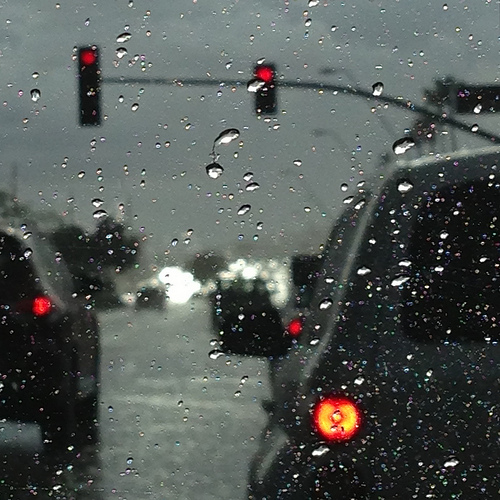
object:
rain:
[180, 117, 262, 191]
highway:
[0, 269, 297, 500]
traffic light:
[257, 65, 274, 83]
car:
[245, 141, 500, 500]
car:
[207, 275, 288, 356]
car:
[0, 220, 102, 458]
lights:
[31, 295, 53, 316]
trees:
[469, 97, 478, 103]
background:
[176, 0, 499, 423]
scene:
[6, 3, 498, 483]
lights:
[79, 49, 98, 64]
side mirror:
[218, 310, 293, 361]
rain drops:
[205, 162, 226, 180]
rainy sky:
[0, 37, 500, 198]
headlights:
[287, 320, 302, 336]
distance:
[131, 279, 171, 312]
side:
[0, 223, 102, 446]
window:
[398, 173, 500, 349]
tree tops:
[460, 84, 465, 92]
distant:
[105, 221, 213, 351]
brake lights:
[314, 393, 363, 445]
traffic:
[4, 98, 499, 499]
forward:
[120, 275, 180, 336]